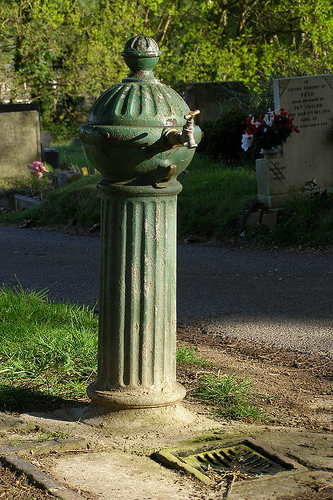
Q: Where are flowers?
A: Near a grave.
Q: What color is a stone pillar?
A: Green.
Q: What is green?
A: Trees.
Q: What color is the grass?
A: Green.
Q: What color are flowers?
A: Red and white.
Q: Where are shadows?
A: On the ground.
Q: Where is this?
A: A cemetery.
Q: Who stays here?
A: Dead people.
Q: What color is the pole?
A: Green.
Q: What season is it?
A: Summer.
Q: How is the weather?
A: Sunny.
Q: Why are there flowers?
A: To honor the dead.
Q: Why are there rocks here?
A: To mark the graves.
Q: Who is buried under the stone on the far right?
A: Fred.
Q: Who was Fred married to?
A: Pat Taylor.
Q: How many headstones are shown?
A: 3.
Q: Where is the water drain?
A: Bottom right.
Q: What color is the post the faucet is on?
A: Green.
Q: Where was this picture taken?
A: At a cemetery.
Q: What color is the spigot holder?
A: Green.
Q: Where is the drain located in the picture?
A: In front of the spigot.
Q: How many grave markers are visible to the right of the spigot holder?
A: Two.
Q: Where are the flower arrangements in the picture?
A: Behind the spigot holder.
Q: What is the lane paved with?
A: Asphalt.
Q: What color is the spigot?
A: Gray.